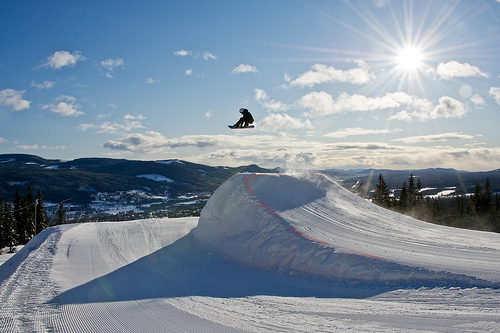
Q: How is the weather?
A: It is sunny.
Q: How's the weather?
A: It is sunny.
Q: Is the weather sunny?
A: Yes, it is sunny.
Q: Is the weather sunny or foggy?
A: It is sunny.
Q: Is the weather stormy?
A: No, it is sunny.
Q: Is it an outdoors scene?
A: Yes, it is outdoors.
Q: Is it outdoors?
A: Yes, it is outdoors.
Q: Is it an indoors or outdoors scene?
A: It is outdoors.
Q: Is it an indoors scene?
A: No, it is outdoors.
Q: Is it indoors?
A: No, it is outdoors.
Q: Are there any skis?
A: No, there are no skis.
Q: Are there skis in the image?
A: No, there are no skis.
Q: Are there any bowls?
A: No, there are no bowls.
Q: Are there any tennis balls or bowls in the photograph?
A: No, there are no bowls or tennis balls.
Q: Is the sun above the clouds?
A: Yes, the sun is above the clouds.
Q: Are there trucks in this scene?
A: No, there are no trucks.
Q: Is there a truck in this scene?
A: No, there are no trucks.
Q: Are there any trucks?
A: No, there are no trucks.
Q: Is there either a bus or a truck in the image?
A: No, there are no trucks or buses.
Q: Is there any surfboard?
A: No, there are no surfboards.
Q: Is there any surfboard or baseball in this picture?
A: No, there are no surfboards or baseballs.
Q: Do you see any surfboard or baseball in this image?
A: No, there are no surfboards or baseballs.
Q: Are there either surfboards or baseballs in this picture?
A: No, there are no surfboards or baseballs.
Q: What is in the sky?
A: The clouds are in the sky.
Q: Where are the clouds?
A: The clouds are in the sky.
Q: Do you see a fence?
A: No, there are no fences.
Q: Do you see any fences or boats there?
A: No, there are no fences or boats.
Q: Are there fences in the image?
A: No, there are no fences.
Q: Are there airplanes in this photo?
A: No, there are no airplanes.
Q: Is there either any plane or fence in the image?
A: No, there are no airplanes or fences.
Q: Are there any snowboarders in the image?
A: Yes, there is a snowboarder.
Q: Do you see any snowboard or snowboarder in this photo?
A: Yes, there is a snowboarder.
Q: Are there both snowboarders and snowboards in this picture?
A: Yes, there are both a snowboarder and a snowboard.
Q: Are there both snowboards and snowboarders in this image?
A: Yes, there are both a snowboarder and a snowboard.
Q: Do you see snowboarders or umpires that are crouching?
A: Yes, the snowboarder is crouching.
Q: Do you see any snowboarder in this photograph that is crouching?
A: Yes, there is a snowboarder that is crouching.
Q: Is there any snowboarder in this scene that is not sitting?
A: Yes, there is a snowboarder that is crouching.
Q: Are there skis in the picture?
A: No, there are no skis.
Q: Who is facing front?
A: The snowboarder is facing front.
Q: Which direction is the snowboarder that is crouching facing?
A: The snowboarder is facing front.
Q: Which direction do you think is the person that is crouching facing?
A: The snowboarder is facing front.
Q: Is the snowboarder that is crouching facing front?
A: Yes, the snowboarder is facing front.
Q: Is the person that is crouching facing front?
A: Yes, the snowboarder is facing front.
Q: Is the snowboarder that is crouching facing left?
A: No, the snowboarder is facing front.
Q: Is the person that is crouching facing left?
A: No, the snowboarder is facing front.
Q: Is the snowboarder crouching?
A: Yes, the snowboarder is crouching.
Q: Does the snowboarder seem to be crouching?
A: Yes, the snowboarder is crouching.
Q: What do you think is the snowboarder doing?
A: The snowboarder is crouching.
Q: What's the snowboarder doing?
A: The snowboarder is crouching.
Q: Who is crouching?
A: The snowboarder is crouching.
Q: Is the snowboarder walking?
A: No, the snowboarder is crouching.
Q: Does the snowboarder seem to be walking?
A: No, the snowboarder is crouching.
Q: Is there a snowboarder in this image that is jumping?
A: No, there is a snowboarder but he is crouching.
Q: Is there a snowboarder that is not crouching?
A: No, there is a snowboarder but he is crouching.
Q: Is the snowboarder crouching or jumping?
A: The snowboarder is crouching.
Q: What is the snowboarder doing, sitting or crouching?
A: The snowboarder is crouching.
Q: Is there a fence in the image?
A: No, there are no fences.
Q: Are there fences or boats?
A: No, there are no fences or boats.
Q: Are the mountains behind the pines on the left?
A: Yes, the mountains are behind the pine trees.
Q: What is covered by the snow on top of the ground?
A: The mountains are covered by the snow.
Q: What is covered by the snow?
A: The mountains are covered by the snow.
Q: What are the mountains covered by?
A: The mountains are covered by the snow.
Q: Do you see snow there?
A: Yes, there is snow.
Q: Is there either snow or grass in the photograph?
A: Yes, there is snow.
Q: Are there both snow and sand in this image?
A: No, there is snow but no sand.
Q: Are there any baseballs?
A: No, there are no baseballs.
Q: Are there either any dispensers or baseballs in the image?
A: No, there are no baseballs or dispensers.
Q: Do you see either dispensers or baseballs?
A: No, there are no baseballs or dispensers.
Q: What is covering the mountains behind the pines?
A: The snow is covering the mountains.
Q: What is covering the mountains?
A: The snow is covering the mountains.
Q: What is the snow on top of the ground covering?
A: The snow is covering the mountains.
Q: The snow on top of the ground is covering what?
A: The snow is covering the mountains.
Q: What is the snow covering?
A: The snow is covering the mountains.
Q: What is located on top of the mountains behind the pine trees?
A: The snow is on top of the mountains.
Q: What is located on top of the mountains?
A: The snow is on top of the mountains.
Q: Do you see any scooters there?
A: No, there are no scooters.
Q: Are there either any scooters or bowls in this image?
A: No, there are no scooters or bowls.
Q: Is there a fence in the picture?
A: No, there are no fences.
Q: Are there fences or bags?
A: No, there are no fences or bags.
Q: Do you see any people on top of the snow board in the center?
A: Yes, there is a person on top of the snowboard.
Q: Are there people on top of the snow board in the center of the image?
A: Yes, there is a person on top of the snowboard.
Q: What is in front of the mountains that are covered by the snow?
A: The pine trees are in front of the mountains.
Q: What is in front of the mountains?
A: The pine trees are in front of the mountains.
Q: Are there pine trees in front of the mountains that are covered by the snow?
A: Yes, there are pine trees in front of the mountains.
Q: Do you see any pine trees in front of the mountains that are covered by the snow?
A: Yes, there are pine trees in front of the mountains.